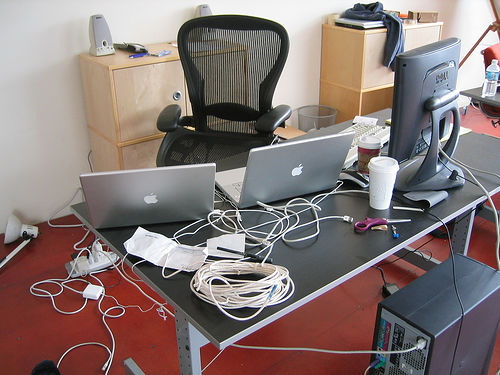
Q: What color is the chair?
A: Black.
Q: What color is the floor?
A: Red.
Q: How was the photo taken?
A: With a telephoto lens.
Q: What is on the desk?
A: A coffee cup.